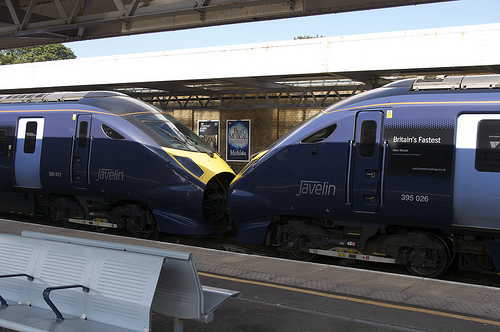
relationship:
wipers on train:
[146, 119, 214, 157] [2, 82, 236, 245]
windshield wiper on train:
[155, 128, 192, 147] [0, 67, 213, 209]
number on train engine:
[400, 192, 430, 202] [225, 72, 498, 286]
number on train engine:
[45, 169, 62, 176] [0, 92, 235, 244]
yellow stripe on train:
[398, 97, 499, 109] [230, 71, 498, 286]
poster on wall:
[221, 116, 252, 166] [154, 101, 347, 187]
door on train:
[347, 105, 387, 217] [230, 71, 498, 286]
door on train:
[12, 114, 46, 189] [230, 71, 498, 286]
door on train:
[68, 112, 95, 187] [2, 82, 236, 245]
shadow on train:
[3, 130, 219, 225] [2, 76, 252, 244]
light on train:
[4, 91, 207, 153] [224, 68, 499, 233]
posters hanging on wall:
[195, 110, 255, 172] [196, 104, 267, 172]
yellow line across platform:
[278, 280, 363, 310] [1, 219, 476, 329]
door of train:
[347, 105, 387, 217] [2, 82, 236, 245]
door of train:
[347, 105, 387, 217] [230, 71, 498, 286]